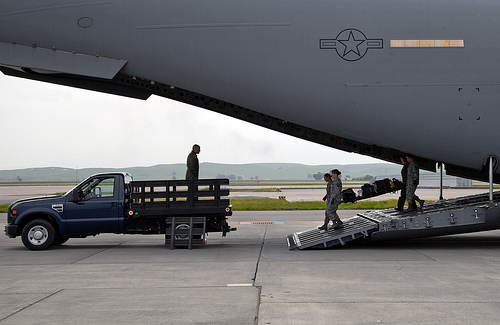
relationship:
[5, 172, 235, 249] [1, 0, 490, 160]
truck under plane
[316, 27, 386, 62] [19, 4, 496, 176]
emblem on plane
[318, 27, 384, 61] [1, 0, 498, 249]
emblem on plane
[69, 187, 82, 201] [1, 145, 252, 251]
mirror on truck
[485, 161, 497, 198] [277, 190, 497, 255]
pole on ramp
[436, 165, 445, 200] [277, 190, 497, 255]
pole on ramp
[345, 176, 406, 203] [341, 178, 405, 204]
body on body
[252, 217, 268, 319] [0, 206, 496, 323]
crack in runway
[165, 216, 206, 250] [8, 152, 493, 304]
chair in ground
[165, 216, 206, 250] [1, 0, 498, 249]
chair near plane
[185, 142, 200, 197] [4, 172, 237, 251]
man standing in back of truck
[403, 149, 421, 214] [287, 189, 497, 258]
serviceman walking down incline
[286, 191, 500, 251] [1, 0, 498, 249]
airplane ramp of plane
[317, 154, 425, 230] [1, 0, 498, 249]
people coming out of plane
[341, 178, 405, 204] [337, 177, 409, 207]
body on stretcher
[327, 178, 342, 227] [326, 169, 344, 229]
uniform on soldier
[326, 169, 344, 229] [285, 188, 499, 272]
soldier on ramp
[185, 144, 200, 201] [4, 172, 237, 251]
man standing in truck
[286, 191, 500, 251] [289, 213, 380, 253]
airplane ramp for people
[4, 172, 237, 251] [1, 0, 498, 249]
truck parked near plane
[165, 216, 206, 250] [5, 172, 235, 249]
chair by truck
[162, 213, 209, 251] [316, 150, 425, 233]
chair before people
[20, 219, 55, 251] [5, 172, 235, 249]
front tire on truck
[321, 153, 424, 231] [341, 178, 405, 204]
people carrying body